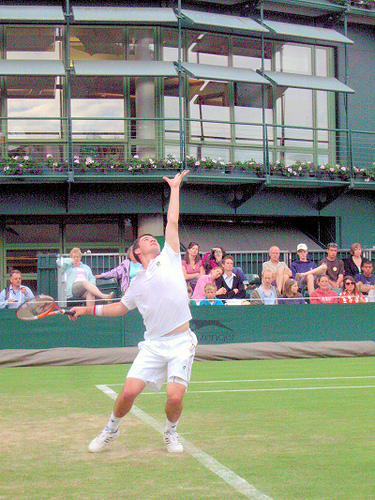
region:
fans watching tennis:
[0, 240, 373, 309]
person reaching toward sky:
[65, 167, 199, 455]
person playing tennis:
[66, 166, 199, 455]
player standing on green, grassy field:
[67, 167, 203, 452]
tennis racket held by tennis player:
[14, 290, 82, 323]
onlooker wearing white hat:
[287, 240, 319, 278]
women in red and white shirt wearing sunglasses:
[337, 273, 367, 303]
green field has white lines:
[1, 354, 374, 498]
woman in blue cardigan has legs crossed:
[51, 243, 115, 308]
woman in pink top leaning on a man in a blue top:
[192, 263, 228, 301]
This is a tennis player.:
[5, 162, 215, 452]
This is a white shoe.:
[163, 410, 178, 460]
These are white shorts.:
[113, 331, 218, 382]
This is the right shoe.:
[72, 423, 139, 470]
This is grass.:
[253, 412, 345, 484]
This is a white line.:
[193, 446, 257, 498]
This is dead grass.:
[15, 431, 77, 482]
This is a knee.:
[155, 387, 198, 415]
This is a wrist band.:
[86, 289, 109, 329]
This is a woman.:
[49, 234, 125, 307]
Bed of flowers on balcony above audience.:
[0, 139, 371, 182]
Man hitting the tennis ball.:
[17, 170, 231, 460]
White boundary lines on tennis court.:
[80, 374, 371, 496]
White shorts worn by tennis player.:
[119, 331, 206, 399]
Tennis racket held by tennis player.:
[6, 291, 80, 327]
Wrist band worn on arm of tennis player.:
[90, 300, 107, 320]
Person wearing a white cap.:
[292, 242, 317, 276]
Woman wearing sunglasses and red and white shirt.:
[338, 274, 369, 304]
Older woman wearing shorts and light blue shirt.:
[57, 244, 100, 308]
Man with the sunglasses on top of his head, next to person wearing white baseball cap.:
[321, 241, 351, 286]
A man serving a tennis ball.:
[15, 171, 198, 454]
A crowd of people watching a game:
[1, 243, 374, 304]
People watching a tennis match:
[1, 242, 374, 302]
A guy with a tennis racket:
[13, 170, 198, 453]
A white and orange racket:
[16, 293, 74, 321]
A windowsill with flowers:
[69, 142, 181, 177]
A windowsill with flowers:
[183, 142, 263, 173]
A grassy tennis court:
[0, 355, 374, 499]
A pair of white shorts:
[125, 329, 195, 387]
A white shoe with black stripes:
[163, 427, 184, 453]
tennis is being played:
[20, 103, 369, 485]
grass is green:
[237, 442, 294, 480]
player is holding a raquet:
[12, 270, 232, 435]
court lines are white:
[92, 367, 195, 494]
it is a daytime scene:
[5, 207, 317, 498]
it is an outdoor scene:
[9, 191, 347, 497]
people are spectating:
[5, 254, 368, 303]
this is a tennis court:
[5, 364, 368, 491]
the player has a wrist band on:
[50, 296, 205, 388]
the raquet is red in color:
[9, 252, 134, 367]